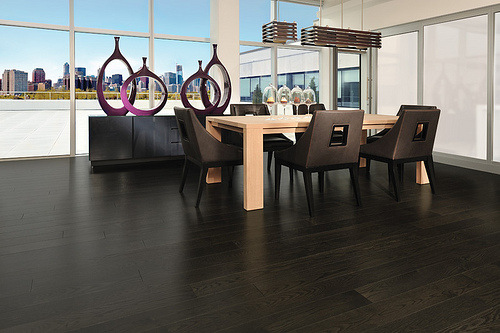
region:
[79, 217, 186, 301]
this is the floor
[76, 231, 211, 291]
the floor is made of wood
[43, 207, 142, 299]
the floor is black in color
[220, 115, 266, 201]
this is a table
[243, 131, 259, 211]
the table is wooden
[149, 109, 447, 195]
these are some chairs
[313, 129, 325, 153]
the chair is black in color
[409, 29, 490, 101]
this is a wall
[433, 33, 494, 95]
the wall is made of glass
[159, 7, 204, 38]
this is the sky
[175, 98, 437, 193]
Brown chairs in the room.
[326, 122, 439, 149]
Square holes in the back of the chairs.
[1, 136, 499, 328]
Dark wood floors in the room.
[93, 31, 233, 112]
Four large vase art pieces on the table.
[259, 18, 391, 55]
Lights hanging from the ceiling.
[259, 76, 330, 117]
Glass decorations on the table.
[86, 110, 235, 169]
Dark wood side table in the room.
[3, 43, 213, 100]
Buildings in the background.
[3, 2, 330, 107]
Blue skies in the background.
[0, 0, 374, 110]
Many windows in the room.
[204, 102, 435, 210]
a white table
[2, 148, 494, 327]
a dark hardwood floor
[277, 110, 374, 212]
a black chair at a table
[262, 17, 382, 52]
drop lights hanging from the ceiling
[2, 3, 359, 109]
a large glass window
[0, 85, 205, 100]
a railing visible outside the window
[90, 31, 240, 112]
four decorations on a side table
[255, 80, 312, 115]
four glasses on a table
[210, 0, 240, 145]
a white post between windows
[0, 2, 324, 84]
a beautiful blue sky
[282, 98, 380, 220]
A black dining chair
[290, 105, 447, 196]
two black dining chairs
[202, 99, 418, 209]
Black chairs aroung a white table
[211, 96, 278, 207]
a white table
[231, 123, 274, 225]
The leg of a table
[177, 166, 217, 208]
The leg of a chair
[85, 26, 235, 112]
round purple vases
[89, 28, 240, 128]
four round purple vases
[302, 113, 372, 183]
the back of a chair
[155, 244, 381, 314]
A black wood floor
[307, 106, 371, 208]
this is a chair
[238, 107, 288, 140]
this is a table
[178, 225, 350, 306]
this is the floor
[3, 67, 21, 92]
this is a building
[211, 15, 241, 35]
this is a pillar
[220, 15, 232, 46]
the pillar is white in color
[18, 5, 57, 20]
this is the sky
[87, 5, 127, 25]
thew sky is blue in color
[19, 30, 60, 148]
this is a transparent wall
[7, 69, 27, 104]
the building is tall